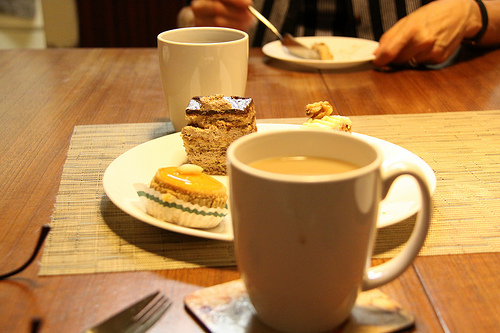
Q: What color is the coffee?
A: Light brown.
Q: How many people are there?
A: One.